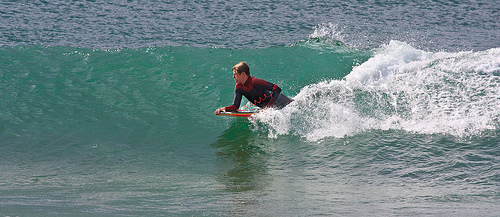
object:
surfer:
[215, 62, 294, 117]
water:
[1, 1, 499, 216]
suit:
[224, 77, 285, 110]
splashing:
[247, 39, 499, 140]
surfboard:
[217, 108, 267, 116]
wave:
[2, 45, 378, 130]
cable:
[237, 88, 275, 111]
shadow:
[206, 117, 266, 194]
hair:
[229, 62, 252, 77]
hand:
[212, 106, 228, 116]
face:
[233, 71, 248, 82]